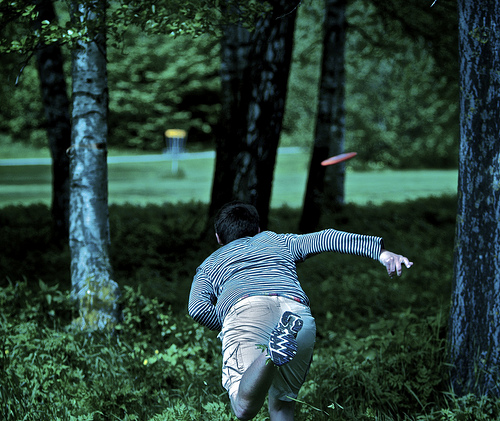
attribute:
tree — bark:
[9, 12, 240, 343]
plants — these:
[53, 354, 141, 398]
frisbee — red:
[320, 150, 358, 166]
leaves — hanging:
[0, 0, 275, 57]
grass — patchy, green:
[1, 137, 493, 419]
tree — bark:
[33, 32, 144, 354]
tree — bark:
[451, 0, 498, 388]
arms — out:
[329, 209, 403, 294]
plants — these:
[132, 250, 161, 355]